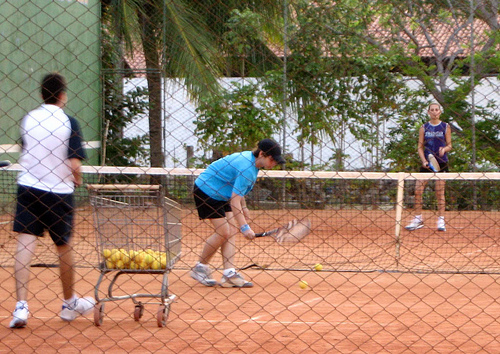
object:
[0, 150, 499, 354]
tennis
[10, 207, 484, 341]
court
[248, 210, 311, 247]
racket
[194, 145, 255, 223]
shirt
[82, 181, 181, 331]
cart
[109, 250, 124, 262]
balls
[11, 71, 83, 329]
man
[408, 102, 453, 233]
woman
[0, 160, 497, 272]
net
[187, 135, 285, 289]
boy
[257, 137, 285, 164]
cap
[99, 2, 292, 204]
tree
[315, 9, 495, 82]
fence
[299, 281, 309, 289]
ball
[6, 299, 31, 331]
shoes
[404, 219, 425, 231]
shoes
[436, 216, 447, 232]
shoe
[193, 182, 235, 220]
shorts